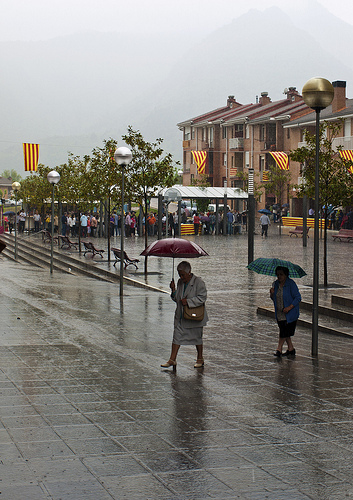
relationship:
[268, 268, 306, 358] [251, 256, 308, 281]
woman holding umbrella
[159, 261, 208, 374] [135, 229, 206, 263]
woman holding umbrella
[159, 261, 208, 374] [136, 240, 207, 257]
woman holding umbrella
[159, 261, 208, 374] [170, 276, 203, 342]
woman wearing a dress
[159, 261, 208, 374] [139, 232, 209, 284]
woman under umbrella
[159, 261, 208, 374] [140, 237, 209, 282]
woman under umbrella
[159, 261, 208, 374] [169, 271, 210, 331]
woman wearing jacket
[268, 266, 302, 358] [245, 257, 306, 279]
woman holding umbrella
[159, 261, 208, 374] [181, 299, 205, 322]
woman holding purse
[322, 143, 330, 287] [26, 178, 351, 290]
tree in park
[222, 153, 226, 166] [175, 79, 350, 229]
window in building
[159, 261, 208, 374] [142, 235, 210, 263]
woman holding umbrella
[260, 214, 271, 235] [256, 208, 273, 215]
woman holding umbrella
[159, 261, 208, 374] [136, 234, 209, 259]
woman holding umbrella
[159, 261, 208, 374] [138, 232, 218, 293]
woman holding umbrella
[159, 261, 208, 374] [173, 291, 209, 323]
woman carrying purse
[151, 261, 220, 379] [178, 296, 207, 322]
woman with purse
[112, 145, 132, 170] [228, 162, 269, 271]
light at pole